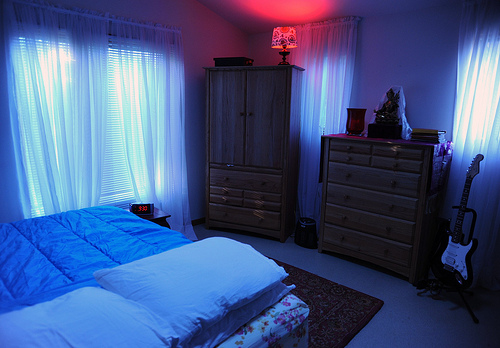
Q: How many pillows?
A: 2.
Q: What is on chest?
A: Lamp.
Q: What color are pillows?
A: White.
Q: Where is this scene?
A: Bedroom.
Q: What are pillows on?
A: Bed.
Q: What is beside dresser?
A: Guitar.